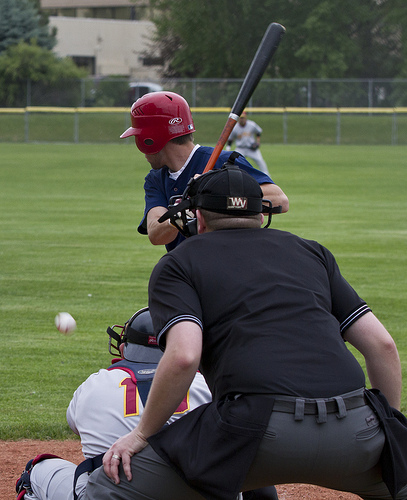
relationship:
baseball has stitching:
[55, 313, 78, 336] [55, 314, 72, 333]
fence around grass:
[0, 76, 406, 147] [0, 141, 406, 439]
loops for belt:
[295, 395, 348, 426] [273, 394, 368, 417]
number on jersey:
[120, 374, 191, 417] [66, 369, 211, 462]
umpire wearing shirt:
[84, 166, 405, 499] [148, 227, 373, 396]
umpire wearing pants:
[84, 166, 405, 499] [82, 388, 405, 498]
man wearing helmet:
[122, 88, 289, 253] [120, 91, 196, 155]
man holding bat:
[122, 88, 289, 253] [202, 21, 287, 175]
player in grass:
[225, 110, 271, 177] [0, 141, 406, 439]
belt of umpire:
[273, 394, 368, 417] [84, 166, 405, 499]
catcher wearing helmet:
[16, 307, 278, 500] [123, 307, 164, 363]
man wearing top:
[122, 88, 289, 253] [138, 145, 275, 251]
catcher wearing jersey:
[16, 307, 278, 500] [66, 369, 211, 462]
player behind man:
[225, 110, 271, 177] [122, 88, 289, 253]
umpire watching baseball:
[84, 166, 405, 499] [55, 313, 78, 336]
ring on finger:
[111, 452, 120, 461] [111, 452, 121, 486]